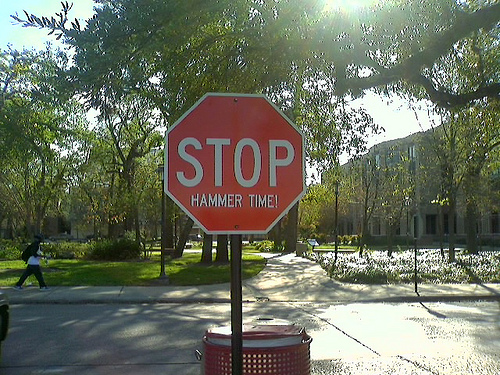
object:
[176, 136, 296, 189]
saying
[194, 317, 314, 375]
can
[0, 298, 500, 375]
street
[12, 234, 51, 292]
man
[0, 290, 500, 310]
curb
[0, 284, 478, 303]
sidewalk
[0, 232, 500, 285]
park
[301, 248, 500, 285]
garden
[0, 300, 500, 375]
roadway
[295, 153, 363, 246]
buildings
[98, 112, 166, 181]
branches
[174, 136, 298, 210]
catchphrase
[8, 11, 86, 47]
branch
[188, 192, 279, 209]
words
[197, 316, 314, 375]
trash bin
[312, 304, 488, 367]
sunlight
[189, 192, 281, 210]
writing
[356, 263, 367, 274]
flowers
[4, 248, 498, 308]
sidewalk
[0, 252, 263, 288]
grass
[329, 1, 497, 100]
branch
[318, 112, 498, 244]
building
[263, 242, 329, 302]
path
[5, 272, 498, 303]
sidewalk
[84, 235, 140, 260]
shrubbery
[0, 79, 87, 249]
trees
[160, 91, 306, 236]
sign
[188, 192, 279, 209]
saying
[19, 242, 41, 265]
shirt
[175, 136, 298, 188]
writing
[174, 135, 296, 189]
words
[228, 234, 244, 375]
post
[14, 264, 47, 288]
pants